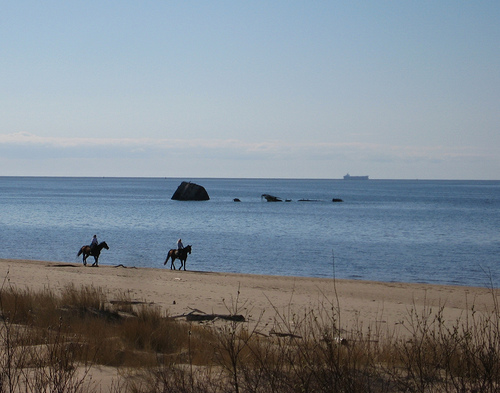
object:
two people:
[90, 235, 185, 259]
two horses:
[77, 244, 192, 271]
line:
[2, 131, 498, 143]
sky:
[2, 0, 498, 176]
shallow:
[5, 202, 495, 245]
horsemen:
[89, 235, 98, 256]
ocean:
[0, 179, 498, 282]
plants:
[216, 328, 497, 386]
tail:
[164, 252, 170, 265]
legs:
[93, 254, 97, 265]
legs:
[82, 253, 85, 263]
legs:
[84, 254, 89, 263]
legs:
[96, 254, 101, 264]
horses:
[77, 241, 109, 267]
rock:
[171, 181, 210, 201]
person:
[177, 239, 184, 259]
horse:
[164, 245, 192, 271]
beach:
[5, 259, 497, 392]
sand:
[261, 291, 397, 299]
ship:
[343, 172, 369, 180]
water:
[4, 178, 86, 213]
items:
[233, 198, 241, 203]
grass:
[11, 290, 480, 390]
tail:
[77, 246, 83, 257]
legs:
[184, 259, 186, 269]